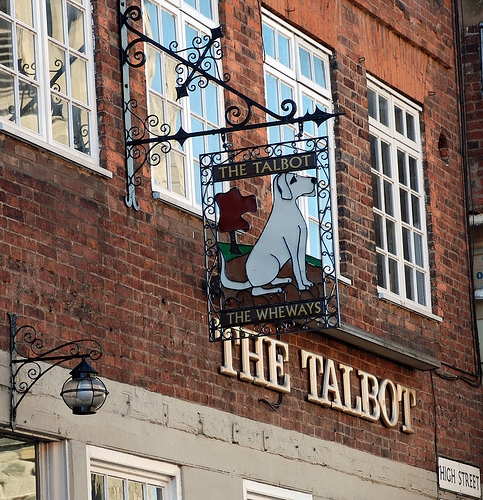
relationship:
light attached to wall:
[4, 307, 113, 439] [2, 244, 164, 441]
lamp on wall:
[7, 312, 109, 430] [1, 345, 481, 498]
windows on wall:
[225, 11, 442, 278] [55, 18, 480, 365]